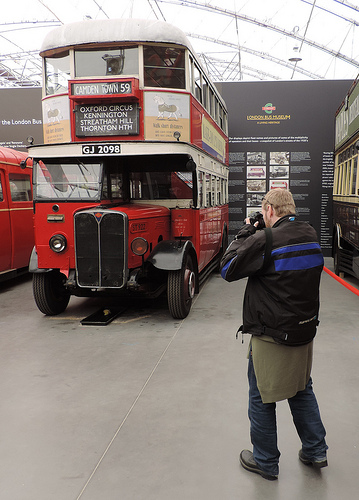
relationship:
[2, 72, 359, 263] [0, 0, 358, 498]
wall of bus museum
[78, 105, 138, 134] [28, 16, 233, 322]
route of bus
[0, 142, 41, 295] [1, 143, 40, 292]
part of another vehicle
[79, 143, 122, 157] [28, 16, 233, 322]
number of bus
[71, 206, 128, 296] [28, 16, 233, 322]
grill of bus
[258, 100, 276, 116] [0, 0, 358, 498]
logo of bus museum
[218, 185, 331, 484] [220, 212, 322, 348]
man in a coat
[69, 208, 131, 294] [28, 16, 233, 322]
radiator of a bus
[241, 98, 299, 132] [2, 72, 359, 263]
sign on wall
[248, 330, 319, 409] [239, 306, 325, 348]
sweater tied around waist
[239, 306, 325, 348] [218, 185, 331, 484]
waist of man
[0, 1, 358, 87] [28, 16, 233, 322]
ceiling above bus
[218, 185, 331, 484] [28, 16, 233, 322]
man taking pictures of bus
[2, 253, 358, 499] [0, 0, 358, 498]
floor in a bus museum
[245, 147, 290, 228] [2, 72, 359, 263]
pictures on wall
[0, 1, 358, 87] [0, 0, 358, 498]
ceiling of bus museum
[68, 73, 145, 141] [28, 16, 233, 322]
sign on bus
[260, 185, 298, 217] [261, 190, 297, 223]
head has hair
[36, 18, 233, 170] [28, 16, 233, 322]
second story on a bus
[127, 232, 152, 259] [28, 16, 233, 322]
headlight on a bus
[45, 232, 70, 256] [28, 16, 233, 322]
headlight on a bus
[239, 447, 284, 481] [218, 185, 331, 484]
left shoe on a man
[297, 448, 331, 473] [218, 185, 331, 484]
right shoe on a man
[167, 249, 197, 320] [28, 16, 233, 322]
tire on a bus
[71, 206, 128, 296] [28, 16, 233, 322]
grill on front of a bus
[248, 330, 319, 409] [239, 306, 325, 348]
sweater around a mans waist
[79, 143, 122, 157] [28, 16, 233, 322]
number on a bus